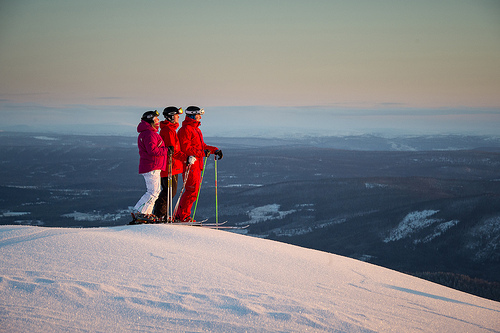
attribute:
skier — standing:
[128, 112, 166, 224]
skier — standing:
[159, 108, 185, 226]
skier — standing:
[176, 105, 224, 225]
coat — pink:
[137, 122, 169, 176]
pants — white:
[136, 167, 163, 215]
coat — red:
[159, 120, 187, 176]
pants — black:
[155, 170, 178, 219]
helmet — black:
[141, 110, 159, 126]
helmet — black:
[163, 105, 181, 120]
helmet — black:
[186, 104, 197, 122]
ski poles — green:
[192, 152, 224, 226]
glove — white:
[188, 154, 195, 165]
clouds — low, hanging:
[13, 102, 495, 131]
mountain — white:
[1, 224, 498, 329]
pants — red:
[174, 153, 204, 227]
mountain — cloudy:
[1, 102, 497, 142]